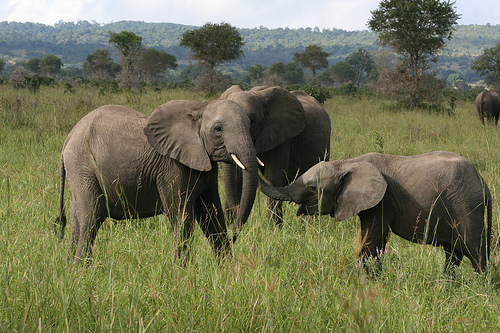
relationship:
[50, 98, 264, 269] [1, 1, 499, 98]
elephant in forest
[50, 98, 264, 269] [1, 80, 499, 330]
elephant in grasslands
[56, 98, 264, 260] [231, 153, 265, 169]
elephant has tusks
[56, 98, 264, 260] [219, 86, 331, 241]
elephant blocking elephant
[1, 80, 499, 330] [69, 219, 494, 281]
grasslands covering feet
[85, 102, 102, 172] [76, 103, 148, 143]
indentation on back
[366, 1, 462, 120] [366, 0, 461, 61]
tree has leaves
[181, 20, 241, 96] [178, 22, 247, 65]
tree has leaves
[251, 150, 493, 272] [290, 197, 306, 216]
elephant has mouth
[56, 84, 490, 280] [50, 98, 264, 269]
family of elephant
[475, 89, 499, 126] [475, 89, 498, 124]
elephant facing away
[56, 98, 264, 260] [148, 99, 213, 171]
elephant has ear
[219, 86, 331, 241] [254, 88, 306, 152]
elephant has ear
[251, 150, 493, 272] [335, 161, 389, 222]
elephant has ear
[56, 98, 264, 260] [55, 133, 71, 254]
elephant has tail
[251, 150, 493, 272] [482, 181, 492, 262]
elephant has tail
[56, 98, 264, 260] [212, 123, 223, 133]
elephant has eye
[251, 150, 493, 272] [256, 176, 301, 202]
elephant has trunk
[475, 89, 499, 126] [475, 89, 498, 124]
elephant walking away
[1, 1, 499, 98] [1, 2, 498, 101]
forest in distance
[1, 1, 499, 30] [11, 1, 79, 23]
sky has clouds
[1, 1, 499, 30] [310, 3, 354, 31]
sky has clouds